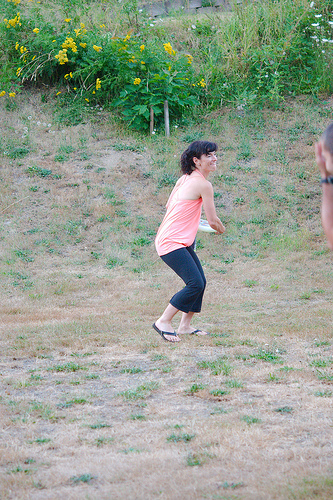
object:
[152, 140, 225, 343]
girl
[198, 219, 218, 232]
frisbee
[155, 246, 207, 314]
pants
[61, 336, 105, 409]
grass